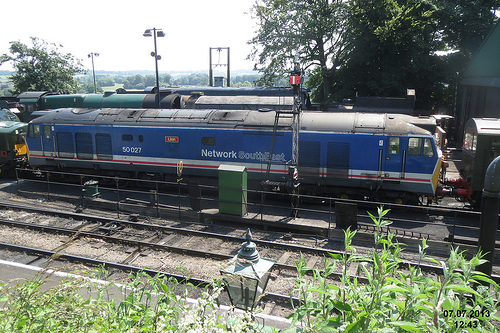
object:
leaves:
[326, 252, 343, 263]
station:
[0, 0, 497, 333]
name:
[200, 149, 238, 159]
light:
[156, 30, 166, 38]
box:
[217, 163, 247, 216]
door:
[326, 141, 351, 180]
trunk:
[319, 63, 333, 102]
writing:
[122, 146, 142, 154]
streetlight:
[94, 52, 100, 57]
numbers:
[138, 148, 142, 154]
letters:
[201, 149, 207, 157]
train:
[23, 107, 453, 189]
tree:
[0, 35, 90, 98]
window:
[56, 131, 74, 159]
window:
[75, 132, 94, 161]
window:
[94, 134, 112, 161]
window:
[297, 141, 320, 177]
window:
[386, 135, 401, 156]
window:
[406, 136, 422, 157]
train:
[15, 101, 453, 224]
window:
[422, 137, 433, 158]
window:
[43, 125, 50, 139]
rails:
[0, 201, 500, 310]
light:
[143, 29, 153, 37]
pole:
[152, 27, 160, 109]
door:
[296, 139, 320, 178]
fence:
[14, 167, 500, 249]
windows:
[120, 133, 133, 141]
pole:
[288, 86, 302, 216]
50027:
[122, 147, 142, 154]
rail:
[1, 185, 481, 330]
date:
[441, 307, 491, 331]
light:
[289, 71, 305, 86]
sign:
[162, 134, 180, 143]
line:
[27, 150, 432, 185]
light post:
[219, 229, 273, 330]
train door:
[381, 135, 405, 184]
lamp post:
[152, 28, 160, 94]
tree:
[250, 0, 497, 136]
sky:
[0, 0, 467, 73]